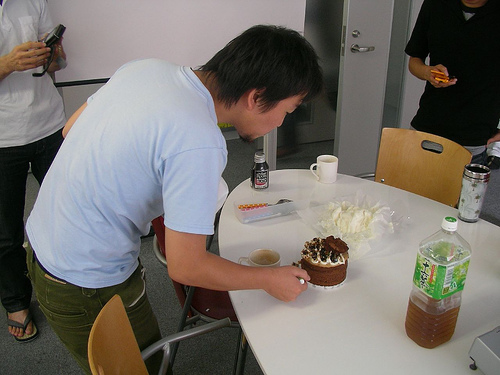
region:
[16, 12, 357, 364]
a man having a dessert to eat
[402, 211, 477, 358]
a bottle half full of a beverage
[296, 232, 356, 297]
a small chocolate cake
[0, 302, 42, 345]
a foot wearing flip flops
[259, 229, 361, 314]
a hand cutting a cake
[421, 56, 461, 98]
the hand of a man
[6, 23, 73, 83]
the hands of a man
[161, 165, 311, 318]
the arm of a man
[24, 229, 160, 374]
the pants of a man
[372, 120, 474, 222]
the back of a chair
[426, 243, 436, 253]
part of a table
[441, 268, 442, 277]
part of a bottle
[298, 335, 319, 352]
edge of a bottle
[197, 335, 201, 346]
part of a chair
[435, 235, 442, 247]
tip of a bottle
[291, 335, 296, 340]
side of a table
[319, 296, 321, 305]
tip of a table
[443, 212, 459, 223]
A green top of the cap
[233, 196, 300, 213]
The fork has a red handle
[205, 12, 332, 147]
A man with a short beard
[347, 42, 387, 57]
A steel handle of the door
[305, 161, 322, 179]
Handle of a plane white cup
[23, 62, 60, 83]
Asmall black strap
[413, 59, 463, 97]
A hand holding a phone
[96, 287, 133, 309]
Edge of the yellow chair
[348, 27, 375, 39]
A steel lock on the door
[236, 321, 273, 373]
Edge of a white table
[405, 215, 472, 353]
a bottle is half full of brown liquid.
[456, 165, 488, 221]
a cup is white and silver.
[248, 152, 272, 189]
a bottle has a cap on.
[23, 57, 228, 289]
a man is wearing a white shirt.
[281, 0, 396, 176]
a door is open.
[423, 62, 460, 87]
a hand is holding a yellow cellphone.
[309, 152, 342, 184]
the mug is white.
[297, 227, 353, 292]
small chocolate cake on a table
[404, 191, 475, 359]
bottle of tea on a table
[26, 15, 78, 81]
camera in a man's hands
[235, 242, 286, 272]
tea cup on a table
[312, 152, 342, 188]
white mug on a table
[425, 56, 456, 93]
cell phone in a man's hand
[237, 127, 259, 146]
goatee on a chin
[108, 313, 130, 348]
wooden back of a chair